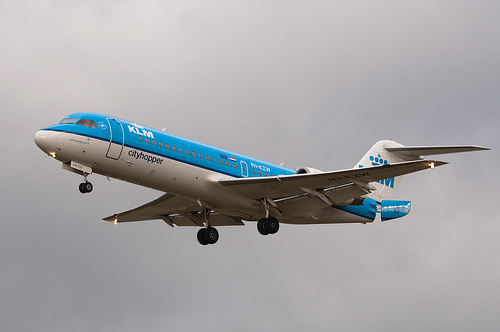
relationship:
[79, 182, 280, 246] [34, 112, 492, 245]
wheels under airplane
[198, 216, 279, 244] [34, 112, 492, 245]
wheels middle of airplane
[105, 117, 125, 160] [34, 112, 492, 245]
door on airplane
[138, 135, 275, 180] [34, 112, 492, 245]
windows on airplane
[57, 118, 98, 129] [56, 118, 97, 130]
windows of cockpit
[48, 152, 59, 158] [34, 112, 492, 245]
light under airplane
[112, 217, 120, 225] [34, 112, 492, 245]
light under airplane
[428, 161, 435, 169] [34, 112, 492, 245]
light under airplane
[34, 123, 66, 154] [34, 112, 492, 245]
nose of airplane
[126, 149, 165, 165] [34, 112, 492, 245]
cityhopper on airplane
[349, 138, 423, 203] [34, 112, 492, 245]
tail on airplane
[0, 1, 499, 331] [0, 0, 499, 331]
clouds in sky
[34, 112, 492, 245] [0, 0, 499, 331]
airplane in sky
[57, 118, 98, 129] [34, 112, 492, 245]
windows on airplane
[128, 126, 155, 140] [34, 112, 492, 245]
klm on airplane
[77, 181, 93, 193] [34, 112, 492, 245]
front wheels under airplane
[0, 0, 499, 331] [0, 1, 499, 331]
sky has clouds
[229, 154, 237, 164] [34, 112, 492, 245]
flag on airplane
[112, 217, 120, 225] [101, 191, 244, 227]
light under wing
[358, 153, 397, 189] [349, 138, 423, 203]
logo on tail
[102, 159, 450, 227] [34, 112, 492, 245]
wings on airplane